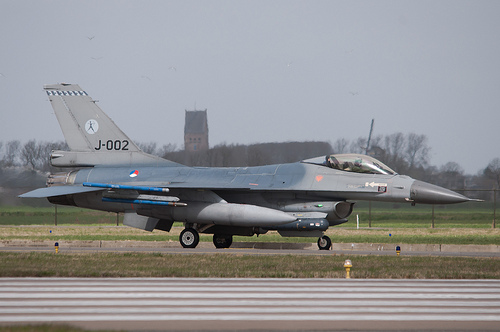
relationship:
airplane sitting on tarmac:
[19, 83, 484, 251] [1, 241, 500, 259]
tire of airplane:
[179, 227, 201, 248] [19, 83, 484, 251]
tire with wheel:
[179, 227, 201, 248] [182, 231, 195, 244]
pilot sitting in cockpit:
[354, 159, 365, 167] [300, 154, 402, 176]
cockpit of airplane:
[300, 154, 402, 176] [19, 83, 484, 251]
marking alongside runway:
[343, 259, 353, 279] [0, 277, 499, 330]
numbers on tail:
[94, 138, 130, 152] [17, 83, 186, 213]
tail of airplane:
[17, 83, 186, 213] [19, 83, 484, 251]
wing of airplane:
[117, 181, 252, 191] [19, 83, 484, 251]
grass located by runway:
[0, 206, 499, 244] [0, 277, 499, 330]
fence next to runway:
[0, 203, 499, 226] [0, 277, 499, 330]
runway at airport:
[0, 277, 499, 330] [3, 204, 499, 329]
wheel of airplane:
[182, 231, 195, 244] [19, 83, 484, 251]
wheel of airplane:
[214, 232, 229, 247] [19, 83, 484, 251]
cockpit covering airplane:
[300, 154, 402, 176] [19, 83, 484, 251]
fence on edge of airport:
[0, 203, 499, 226] [3, 204, 499, 329]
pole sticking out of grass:
[356, 213, 361, 229] [0, 206, 499, 244]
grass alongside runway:
[1, 251, 500, 279] [0, 277, 499, 330]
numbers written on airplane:
[94, 138, 130, 152] [19, 83, 484, 251]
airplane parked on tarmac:
[19, 83, 484, 251] [1, 241, 500, 259]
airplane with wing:
[19, 83, 484, 251] [117, 181, 252, 191]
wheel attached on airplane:
[182, 231, 195, 244] [19, 83, 484, 251]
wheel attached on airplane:
[214, 232, 229, 247] [19, 83, 484, 251]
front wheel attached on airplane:
[316, 235, 331, 250] [19, 83, 484, 251]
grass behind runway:
[0, 206, 499, 244] [0, 277, 499, 330]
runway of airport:
[0, 277, 499, 330] [3, 204, 499, 329]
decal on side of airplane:
[128, 167, 139, 178] [19, 83, 484, 251]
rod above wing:
[82, 181, 170, 192] [117, 181, 252, 191]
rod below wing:
[103, 196, 188, 207] [117, 181, 252, 191]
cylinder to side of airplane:
[136, 202, 297, 222] [19, 83, 484, 251]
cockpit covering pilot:
[300, 154, 402, 176] [354, 159, 365, 167]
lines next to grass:
[1, 276, 500, 324] [1, 251, 500, 279]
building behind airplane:
[165, 110, 333, 168] [19, 83, 484, 251]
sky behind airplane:
[1, 1, 500, 175] [19, 83, 484, 251]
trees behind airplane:
[0, 141, 71, 172] [19, 83, 484, 251]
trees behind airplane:
[335, 134, 431, 168] [19, 83, 484, 251]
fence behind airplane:
[0, 203, 499, 226] [19, 83, 484, 251]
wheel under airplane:
[182, 231, 195, 244] [19, 83, 484, 251]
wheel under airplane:
[214, 232, 229, 247] [19, 83, 484, 251]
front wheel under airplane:
[316, 235, 331, 250] [19, 83, 484, 251]